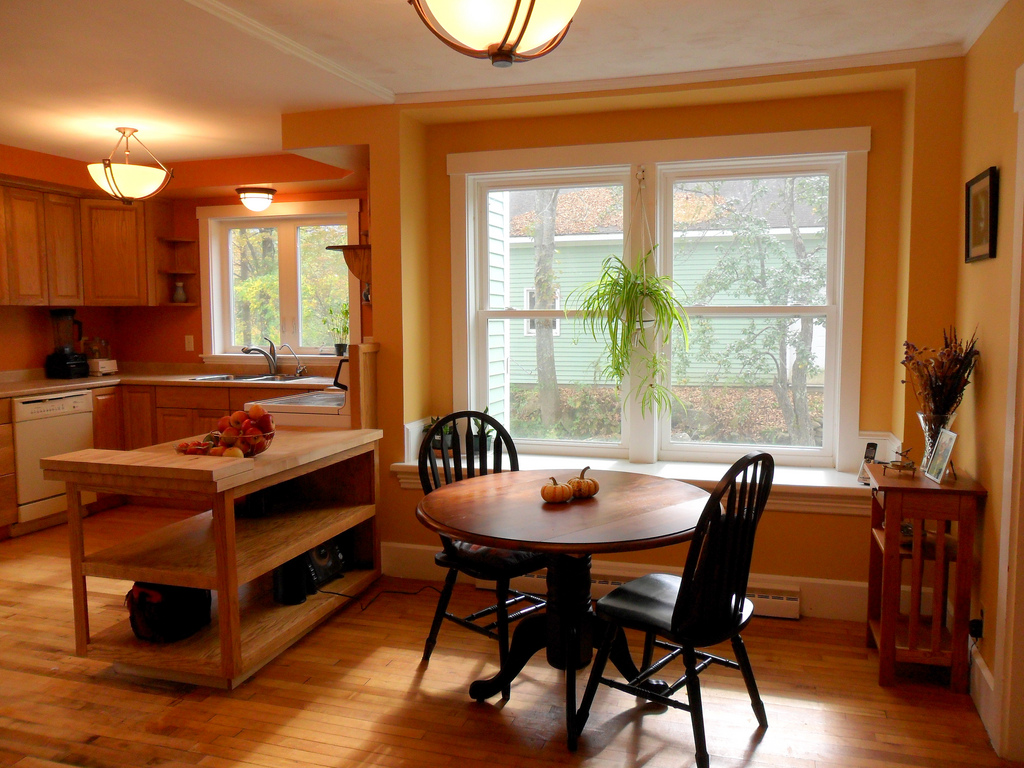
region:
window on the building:
[507, 230, 599, 304]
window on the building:
[523, 357, 625, 459]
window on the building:
[311, 249, 334, 336]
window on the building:
[225, 228, 287, 350]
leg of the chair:
[748, 673, 780, 728]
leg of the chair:
[564, 691, 600, 734]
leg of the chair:
[646, 685, 678, 720]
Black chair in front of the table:
[411, 401, 555, 687]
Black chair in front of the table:
[557, 446, 772, 766]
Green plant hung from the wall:
[579, 161, 697, 430]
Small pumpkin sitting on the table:
[538, 465, 574, 501]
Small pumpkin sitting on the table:
[564, 459, 602, 498]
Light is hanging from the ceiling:
[83, 121, 176, 211]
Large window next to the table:
[459, 143, 849, 475]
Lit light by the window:
[229, 179, 283, 221]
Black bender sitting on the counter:
[39, 298, 84, 378]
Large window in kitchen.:
[446, 155, 859, 470]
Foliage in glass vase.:
[896, 329, 973, 473]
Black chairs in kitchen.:
[612, 447, 772, 748]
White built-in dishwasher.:
[10, 383, 97, 519]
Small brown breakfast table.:
[413, 450, 715, 741]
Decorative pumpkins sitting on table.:
[536, 460, 594, 499]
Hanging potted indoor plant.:
[590, 159, 680, 384]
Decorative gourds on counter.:
[182, 400, 274, 461]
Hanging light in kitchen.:
[78, 127, 168, 201]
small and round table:
[380, 452, 710, 700]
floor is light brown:
[321, 633, 443, 761]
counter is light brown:
[61, 320, 336, 653]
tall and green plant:
[567, 250, 689, 416]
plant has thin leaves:
[564, 235, 695, 401]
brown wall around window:
[839, 51, 988, 244]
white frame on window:
[435, 171, 812, 448]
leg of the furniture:
[735, 699, 770, 735]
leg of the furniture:
[686, 720, 710, 758]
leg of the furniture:
[554, 717, 597, 738]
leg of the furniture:
[629, 685, 658, 715]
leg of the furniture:
[552, 688, 594, 736]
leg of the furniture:
[473, 670, 506, 696]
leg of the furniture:
[492, 622, 515, 665]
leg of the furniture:
[876, 655, 897, 682]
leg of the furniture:
[921, 658, 973, 693]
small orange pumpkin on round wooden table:
[539, 470, 571, 503]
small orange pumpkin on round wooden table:
[570, 466, 597, 496]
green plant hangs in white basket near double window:
[570, 157, 687, 417]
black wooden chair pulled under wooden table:
[563, 456, 780, 766]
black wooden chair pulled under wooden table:
[416, 407, 544, 705]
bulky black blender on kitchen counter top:
[42, 311, 87, 379]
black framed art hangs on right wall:
[958, 165, 997, 268]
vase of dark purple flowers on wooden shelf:
[898, 325, 981, 482]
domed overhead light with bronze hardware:
[86, 125, 173, 205]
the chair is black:
[411, 410, 549, 693]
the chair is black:
[573, 444, 773, 764]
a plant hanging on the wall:
[582, 278, 691, 376]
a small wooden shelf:
[874, 461, 976, 671]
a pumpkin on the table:
[537, 474, 573, 501]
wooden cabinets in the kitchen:
[6, 195, 153, 295]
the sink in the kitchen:
[190, 341, 304, 386]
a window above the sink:
[220, 217, 353, 361]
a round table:
[416, 414, 761, 713]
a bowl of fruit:
[173, 407, 281, 453]